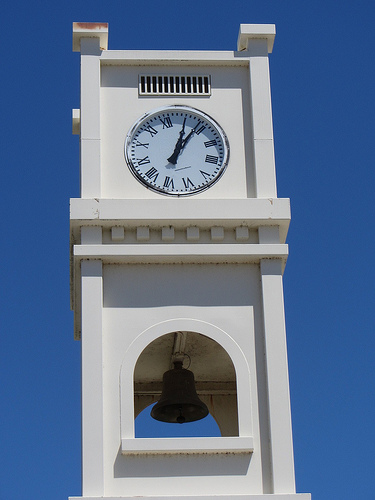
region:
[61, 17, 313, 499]
A clock and bell tower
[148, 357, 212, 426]
A bell in a tower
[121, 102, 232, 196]
A clock on a tower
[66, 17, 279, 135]
The top of a clock tower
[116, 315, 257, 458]
The window of a bell tower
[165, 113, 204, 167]
The hands of a clock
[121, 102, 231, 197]
A clock with roman numerals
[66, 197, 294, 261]
The ledges of a clock tower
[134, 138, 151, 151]
A roman numeral ten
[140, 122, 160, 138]
A roman numeral eleven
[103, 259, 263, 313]
this is a tower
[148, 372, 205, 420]
this is a bell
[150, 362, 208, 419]
the bell is big in size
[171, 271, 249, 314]
the tower is white in color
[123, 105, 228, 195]
this is the clock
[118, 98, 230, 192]
the clock is round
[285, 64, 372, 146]
this is the sky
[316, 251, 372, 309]
the sky is clear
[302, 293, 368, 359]
the sky is blue in color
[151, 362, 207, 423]
the bell is metallic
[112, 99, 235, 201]
big white clock on a tower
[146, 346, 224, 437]
the bell on the tower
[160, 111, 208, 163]
the hands of the clock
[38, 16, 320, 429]
white clock tower with bell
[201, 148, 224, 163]
the roman numeral four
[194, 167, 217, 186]
the roman numeral five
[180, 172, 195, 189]
the roman numeral six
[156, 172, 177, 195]
the roman numeral 7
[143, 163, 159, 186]
the roman numeral eight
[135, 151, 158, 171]
the roman numeral nine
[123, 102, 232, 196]
a metal clock on a tower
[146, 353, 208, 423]
a large bell in a tower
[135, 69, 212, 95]
a grate in a tower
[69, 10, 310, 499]
a large white tower with a bell and a clock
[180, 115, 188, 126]
the roman numeral 1 on a clock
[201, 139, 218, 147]
the roman numeral 3 on a clock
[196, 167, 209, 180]
the roman numeral 5 on a clock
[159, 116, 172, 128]
the roman numeral 12 on a clock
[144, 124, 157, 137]
the roman numeral 11 on a clock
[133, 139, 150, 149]
the roman numeral 10 on a clock